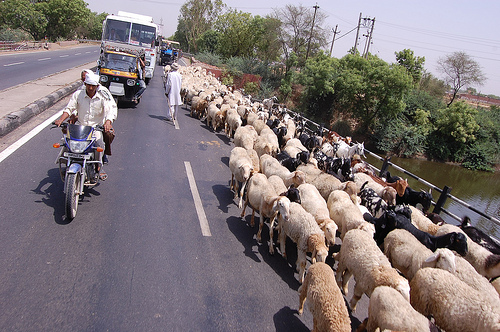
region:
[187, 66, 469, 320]
sheep being herd down the road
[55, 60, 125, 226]
man on a motorcycle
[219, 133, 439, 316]
white sheep with black sheep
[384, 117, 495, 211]
river under the bridge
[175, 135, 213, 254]
white dash in the road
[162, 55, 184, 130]
man in white herding sheep down the road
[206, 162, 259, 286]
sheep shadows on the road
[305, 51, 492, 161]
trees growing on the riverbank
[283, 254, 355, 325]
tan sheep leading the pack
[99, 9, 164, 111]
traffic getting stuck behind the sheep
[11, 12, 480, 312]
a busy highway with cars and animal herds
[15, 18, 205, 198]
busy traffic along the road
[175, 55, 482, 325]
a lot of sheep on the road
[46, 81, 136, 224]
a motorcycle is leading traffic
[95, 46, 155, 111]
a black vehicle on the road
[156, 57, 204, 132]
a sheep herder on the road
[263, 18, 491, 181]
lots of trees in the background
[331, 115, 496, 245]
water under the bridge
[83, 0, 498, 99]
he sky is overcast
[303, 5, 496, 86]
electricity lines in the background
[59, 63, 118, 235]
young motorcycle rider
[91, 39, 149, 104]
third world taxi cab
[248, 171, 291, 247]
one white sheep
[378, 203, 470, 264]
one black sheep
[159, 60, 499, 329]
large group of sheep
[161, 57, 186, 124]
sheep header dressed in white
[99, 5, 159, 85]
large RV type camper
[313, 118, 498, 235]
dirty brown river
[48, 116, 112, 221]
blue and gray motorcycle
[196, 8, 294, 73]
large tree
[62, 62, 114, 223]
2 men on a motorcycle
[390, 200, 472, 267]
a black sheep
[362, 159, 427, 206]
brown goat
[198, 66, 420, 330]
a lot of sheep and goats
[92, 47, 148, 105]
car is small for the driver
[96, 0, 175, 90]
a bus on the road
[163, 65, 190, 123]
this man is walking against the flow of traffic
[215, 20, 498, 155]
a very tranquil view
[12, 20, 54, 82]
less traffic in this direction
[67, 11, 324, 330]
a very busy rush hour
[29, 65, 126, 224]
a man riding on a motorcycle.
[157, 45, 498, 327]
a herd of sheep walking down a road.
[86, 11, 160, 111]
a white truck driving down a road.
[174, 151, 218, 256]
a line in the center of a road.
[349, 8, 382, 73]
a very tall power pole.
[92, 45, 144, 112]
a car driving down a street.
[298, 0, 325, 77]
a tall power line.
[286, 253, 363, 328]
an animal covered in fur.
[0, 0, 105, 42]
a field of green grass.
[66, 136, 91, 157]
a headlight on a bike.